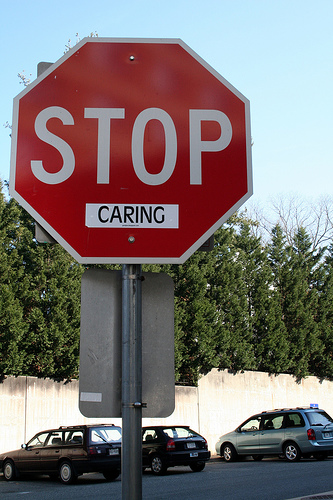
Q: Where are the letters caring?
A: On stop sign.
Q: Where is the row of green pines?
A: Above the wall.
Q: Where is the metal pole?
A: Below the stop sign.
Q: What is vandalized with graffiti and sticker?
A: Red and white stop sign.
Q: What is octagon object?
A: Red and white stop sign.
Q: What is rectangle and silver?
A: Back of sign.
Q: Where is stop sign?
A: Top of backwards sign.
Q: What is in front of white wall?
A: Three cars parked.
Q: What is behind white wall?
A: Trees.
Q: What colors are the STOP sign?
A: Red, White.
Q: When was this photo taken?
A: Daytime.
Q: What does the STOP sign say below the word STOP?
A: CARING.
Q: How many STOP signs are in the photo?
A: One.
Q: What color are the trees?
A: Green.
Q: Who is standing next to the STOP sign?
A: No one.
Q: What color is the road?
A: Grey.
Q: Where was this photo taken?
A: On the street.